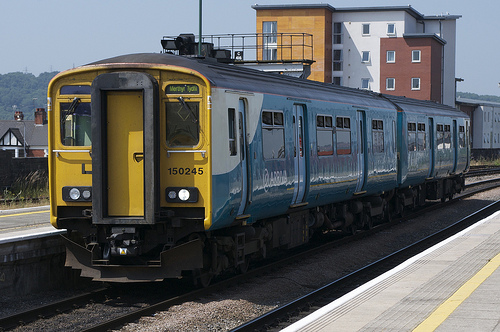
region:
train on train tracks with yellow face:
[36, 50, 475, 288]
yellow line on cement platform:
[408, 252, 495, 330]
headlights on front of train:
[59, 181, 198, 205]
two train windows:
[311, 108, 356, 160]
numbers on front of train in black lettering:
[165, 163, 205, 178]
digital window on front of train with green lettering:
[161, 79, 203, 97]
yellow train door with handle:
[91, 81, 149, 219]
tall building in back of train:
[247, 1, 466, 105]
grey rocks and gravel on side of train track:
[159, 308, 226, 325]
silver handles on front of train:
[163, 145, 208, 159]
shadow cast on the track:
[191, 205, 357, 282]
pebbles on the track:
[162, 302, 243, 321]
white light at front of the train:
[162, 182, 204, 209]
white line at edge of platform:
[340, 271, 429, 301]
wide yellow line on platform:
[409, 282, 478, 319]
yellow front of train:
[46, 56, 231, 216]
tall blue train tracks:
[213, 274, 339, 307]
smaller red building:
[363, 27, 460, 119]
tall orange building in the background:
[246, 6, 345, 81]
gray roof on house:
[9, 110, 42, 148]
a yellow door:
[91, 95, 151, 220]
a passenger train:
[67, 62, 475, 219]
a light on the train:
[166, 182, 198, 204]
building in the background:
[245, 4, 469, 84]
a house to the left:
[4, 110, 55, 170]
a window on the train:
[60, 97, 99, 157]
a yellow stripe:
[454, 247, 490, 330]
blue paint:
[232, 98, 476, 178]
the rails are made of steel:
[42, 280, 152, 330]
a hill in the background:
[4, 65, 51, 102]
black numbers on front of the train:
[169, 165, 211, 181]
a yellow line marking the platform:
[443, 297, 460, 314]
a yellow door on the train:
[100, 90, 149, 227]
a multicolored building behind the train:
[260, 7, 448, 91]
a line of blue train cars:
[225, 95, 468, 191]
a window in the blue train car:
[254, 101, 296, 165]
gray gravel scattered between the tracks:
[174, 305, 237, 330]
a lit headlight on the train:
[176, 185, 201, 202]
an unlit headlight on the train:
[59, 181, 82, 203]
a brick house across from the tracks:
[0, 108, 42, 155]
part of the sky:
[459, 18, 484, 53]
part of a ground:
[196, 291, 230, 318]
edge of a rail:
[311, 282, 330, 297]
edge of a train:
[189, 135, 223, 225]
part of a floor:
[381, 272, 411, 306]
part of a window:
[260, 124, 280, 156]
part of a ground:
[191, 290, 215, 319]